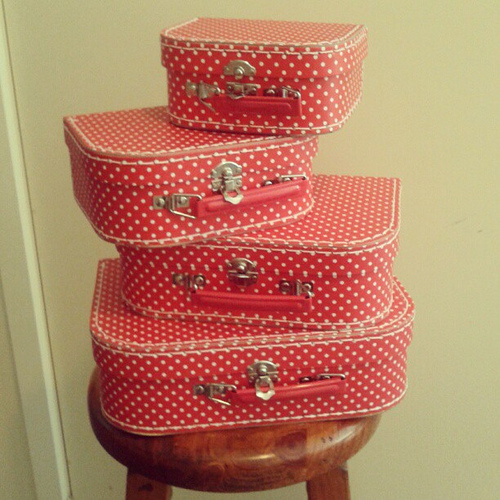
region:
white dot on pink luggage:
[110, 350, 119, 355]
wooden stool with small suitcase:
[86, 363, 383, 499]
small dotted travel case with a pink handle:
[115, 175, 400, 327]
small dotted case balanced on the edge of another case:
[63, 105, 317, 245]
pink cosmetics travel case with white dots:
[160, 15, 369, 135]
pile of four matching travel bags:
[61, 16, 418, 434]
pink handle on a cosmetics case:
[194, 92, 302, 117]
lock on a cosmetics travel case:
[220, 57, 262, 102]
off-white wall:
[363, 0, 498, 176]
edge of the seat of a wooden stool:
[93, 423, 409, 492]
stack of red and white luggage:
[113, 54, 348, 402]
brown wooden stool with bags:
[236, 441, 291, 488]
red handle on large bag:
[226, 389, 331, 408]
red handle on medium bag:
[190, 283, 310, 321]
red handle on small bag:
[168, 193, 317, 230]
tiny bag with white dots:
[142, 3, 353, 143]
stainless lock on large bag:
[241, 355, 271, 394]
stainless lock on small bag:
[203, 160, 241, 204]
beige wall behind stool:
[427, 339, 454, 383]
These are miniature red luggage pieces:
[188, 16, 327, 161]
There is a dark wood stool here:
[283, 439, 294, 464]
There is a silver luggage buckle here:
[249, 354, 273, 402]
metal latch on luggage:
[213, 47, 263, 84]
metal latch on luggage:
[205, 154, 243, 188]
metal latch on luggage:
[220, 250, 257, 290]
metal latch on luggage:
[241, 353, 288, 420]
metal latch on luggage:
[183, 373, 240, 410]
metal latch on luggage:
[287, 358, 351, 395]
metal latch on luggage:
[274, 263, 324, 313]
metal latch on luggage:
[166, 265, 215, 304]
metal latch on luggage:
[139, 175, 214, 233]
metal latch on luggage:
[255, 153, 313, 201]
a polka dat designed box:
[142, 1, 380, 137]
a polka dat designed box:
[54, 104, 331, 262]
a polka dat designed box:
[74, 195, 429, 326]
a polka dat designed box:
[60, 223, 435, 429]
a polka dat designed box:
[137, 8, 394, 161]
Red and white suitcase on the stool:
[161, 15, 368, 134]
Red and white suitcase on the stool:
[85, 252, 411, 447]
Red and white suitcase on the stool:
[101, 175, 408, 335]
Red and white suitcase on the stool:
[60, 111, 288, 245]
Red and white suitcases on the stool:
[61, 23, 416, 438]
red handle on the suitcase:
[193, 373, 349, 408]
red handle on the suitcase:
[179, 273, 321, 323]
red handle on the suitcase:
[155, 170, 307, 223]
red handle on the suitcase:
[189, 79, 302, 120]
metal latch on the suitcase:
[241, 358, 278, 399]